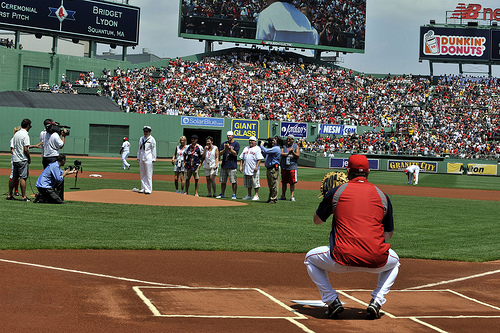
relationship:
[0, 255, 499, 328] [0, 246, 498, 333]
lines are on dirt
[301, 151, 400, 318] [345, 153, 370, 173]
catcher wearing a cap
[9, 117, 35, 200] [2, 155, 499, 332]
man on field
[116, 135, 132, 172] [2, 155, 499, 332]
man on field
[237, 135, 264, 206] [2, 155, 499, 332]
man on field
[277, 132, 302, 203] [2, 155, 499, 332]
man on field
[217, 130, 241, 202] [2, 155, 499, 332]
man on field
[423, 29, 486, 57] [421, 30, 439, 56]
logo has a cup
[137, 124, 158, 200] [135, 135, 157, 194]
man wearing uniform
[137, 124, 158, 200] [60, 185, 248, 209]
man standing on pitcher's mound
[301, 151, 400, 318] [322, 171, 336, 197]
catcher wearing a glove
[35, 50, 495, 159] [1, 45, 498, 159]
people are in baseball stadium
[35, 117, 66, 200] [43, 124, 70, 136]
man has a camera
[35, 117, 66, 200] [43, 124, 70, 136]
man holding camera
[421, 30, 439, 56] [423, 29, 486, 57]
cup on logo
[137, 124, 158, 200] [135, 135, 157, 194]
man wearing a uniform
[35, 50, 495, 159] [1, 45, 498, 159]
spectators are in stadium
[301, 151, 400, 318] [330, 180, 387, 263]
catcher has a back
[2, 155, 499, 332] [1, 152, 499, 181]
field has an edge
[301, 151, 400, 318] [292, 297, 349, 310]
catcher at home plate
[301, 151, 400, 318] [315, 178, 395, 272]
catcher wearing a shirt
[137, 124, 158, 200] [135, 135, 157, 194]
man wearing a sailor suit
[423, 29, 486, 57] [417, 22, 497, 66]
logo on a billboard